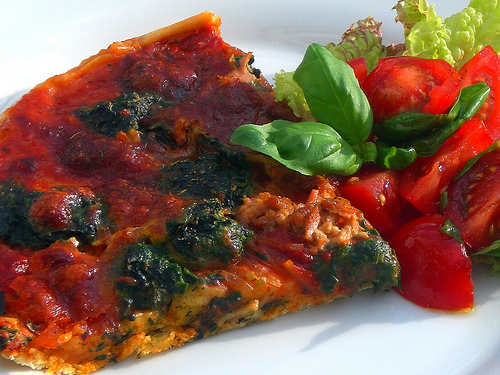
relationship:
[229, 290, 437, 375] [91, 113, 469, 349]
plate on which food sits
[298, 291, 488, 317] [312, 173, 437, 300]
shadow from food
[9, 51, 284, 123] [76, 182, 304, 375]
crust of pizza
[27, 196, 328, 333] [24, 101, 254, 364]
cheese on pizza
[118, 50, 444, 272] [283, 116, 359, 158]
green leaves with veggies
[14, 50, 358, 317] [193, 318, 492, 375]
slice of pizza on white surface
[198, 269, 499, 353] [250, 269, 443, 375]
shadow of veggies being cast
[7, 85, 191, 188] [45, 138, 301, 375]
red tomato sauce on pizza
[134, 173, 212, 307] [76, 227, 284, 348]
green spinach on tomato sauce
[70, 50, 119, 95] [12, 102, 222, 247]
golden crust on slice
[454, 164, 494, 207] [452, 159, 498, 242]
seeds of tomato within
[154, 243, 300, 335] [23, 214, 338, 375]
melted cheese on slice